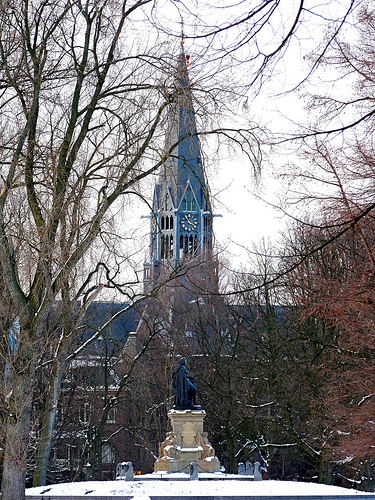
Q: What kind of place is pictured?
A: It is a town.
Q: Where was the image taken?
A: It was taken at the town.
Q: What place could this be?
A: It is a town.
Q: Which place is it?
A: It is a town.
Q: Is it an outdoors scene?
A: Yes, it is outdoors.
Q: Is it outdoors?
A: Yes, it is outdoors.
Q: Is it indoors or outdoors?
A: It is outdoors.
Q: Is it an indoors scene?
A: No, it is outdoors.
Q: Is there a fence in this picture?
A: No, there are no fences.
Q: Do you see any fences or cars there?
A: No, there are no fences or cars.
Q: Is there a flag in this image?
A: No, there are no flags.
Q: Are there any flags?
A: No, there are no flags.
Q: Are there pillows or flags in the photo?
A: No, there are no flags or pillows.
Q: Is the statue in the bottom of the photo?
A: Yes, the statue is in the bottom of the image.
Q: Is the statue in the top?
A: No, the statue is in the bottom of the image.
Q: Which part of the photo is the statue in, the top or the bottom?
A: The statue is in the bottom of the image.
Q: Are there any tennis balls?
A: No, there are no tennis balls.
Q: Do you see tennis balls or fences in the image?
A: No, there are no tennis balls or fences.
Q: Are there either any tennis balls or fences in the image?
A: No, there are no tennis balls or fences.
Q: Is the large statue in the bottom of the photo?
A: Yes, the statue is in the bottom of the image.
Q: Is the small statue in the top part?
A: No, the statue is in the bottom of the image.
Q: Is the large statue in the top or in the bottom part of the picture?
A: The statue is in the bottom of the image.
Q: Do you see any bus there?
A: No, there are no buses.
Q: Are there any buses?
A: No, there are no buses.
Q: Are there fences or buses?
A: No, there are no buses or fences.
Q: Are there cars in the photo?
A: No, there are no cars.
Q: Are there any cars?
A: No, there are no cars.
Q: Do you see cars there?
A: No, there are no cars.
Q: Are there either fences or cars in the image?
A: No, there are no cars or fences.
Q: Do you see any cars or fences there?
A: No, there are no cars or fences.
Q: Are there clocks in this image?
A: Yes, there is a clock.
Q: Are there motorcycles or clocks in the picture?
A: Yes, there is a clock.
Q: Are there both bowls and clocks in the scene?
A: No, there is a clock but no bowls.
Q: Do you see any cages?
A: No, there are no cages.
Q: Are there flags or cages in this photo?
A: No, there are no cages or flags.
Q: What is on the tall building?
A: The clock is on the building.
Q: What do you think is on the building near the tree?
A: The clock is on the building.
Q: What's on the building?
A: The clock is on the building.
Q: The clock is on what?
A: The clock is on the building.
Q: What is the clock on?
A: The clock is on the building.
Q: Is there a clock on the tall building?
A: Yes, there is a clock on the building.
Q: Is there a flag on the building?
A: No, there is a clock on the building.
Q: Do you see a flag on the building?
A: No, there is a clock on the building.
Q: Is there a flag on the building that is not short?
A: No, there is a clock on the building.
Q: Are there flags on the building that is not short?
A: No, there is a clock on the building.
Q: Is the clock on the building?
A: Yes, the clock is on the building.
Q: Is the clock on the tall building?
A: Yes, the clock is on the building.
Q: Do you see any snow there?
A: Yes, there is snow.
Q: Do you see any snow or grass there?
A: Yes, there is snow.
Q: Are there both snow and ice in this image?
A: No, there is snow but no ice.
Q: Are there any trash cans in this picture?
A: No, there are no trash cans.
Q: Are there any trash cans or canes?
A: No, there are no trash cans or canes.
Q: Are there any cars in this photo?
A: No, there are no cars.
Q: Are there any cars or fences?
A: No, there are no cars or fences.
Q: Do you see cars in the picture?
A: No, there are no cars.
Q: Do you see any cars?
A: No, there are no cars.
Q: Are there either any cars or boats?
A: No, there are no cars or boats.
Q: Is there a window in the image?
A: Yes, there are windows.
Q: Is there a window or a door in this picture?
A: Yes, there are windows.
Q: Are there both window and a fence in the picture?
A: No, there are windows but no fences.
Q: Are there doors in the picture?
A: No, there are no doors.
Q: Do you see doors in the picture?
A: No, there are no doors.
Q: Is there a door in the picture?
A: No, there are no doors.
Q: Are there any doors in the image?
A: No, there are no doors.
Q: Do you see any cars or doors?
A: No, there are no doors or cars.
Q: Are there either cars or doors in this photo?
A: No, there are no doors or cars.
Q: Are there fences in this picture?
A: No, there are no fences.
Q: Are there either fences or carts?
A: No, there are no fences or carts.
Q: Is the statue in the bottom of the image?
A: Yes, the statue is in the bottom of the image.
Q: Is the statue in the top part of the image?
A: No, the statue is in the bottom of the image.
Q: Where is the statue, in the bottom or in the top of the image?
A: The statue is in the bottom of the image.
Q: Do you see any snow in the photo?
A: Yes, there is snow.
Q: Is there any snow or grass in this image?
A: Yes, there is snow.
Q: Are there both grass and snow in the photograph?
A: No, there is snow but no grass.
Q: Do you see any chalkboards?
A: No, there are no chalkboards.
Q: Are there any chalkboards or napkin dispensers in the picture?
A: No, there are no chalkboards or napkin dispensers.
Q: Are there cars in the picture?
A: No, there are no cars.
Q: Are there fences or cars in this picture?
A: No, there are no cars or fences.